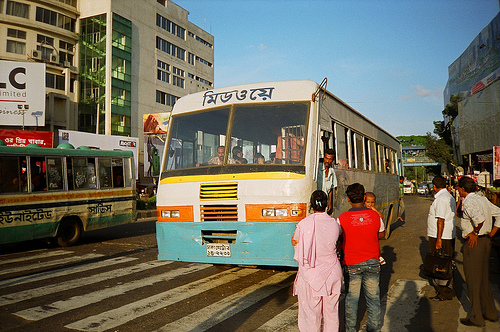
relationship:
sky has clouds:
[224, 17, 442, 110] [383, 76, 459, 108]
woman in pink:
[297, 187, 333, 330] [283, 200, 365, 323]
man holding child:
[336, 182, 389, 328] [365, 192, 376, 208]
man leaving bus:
[336, 182, 389, 328] [143, 71, 418, 243]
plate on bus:
[195, 240, 249, 269] [143, 71, 418, 243]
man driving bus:
[336, 182, 389, 328] [143, 71, 418, 243]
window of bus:
[232, 102, 314, 165] [143, 71, 418, 243]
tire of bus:
[52, 212, 85, 248] [3, 133, 142, 237]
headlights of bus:
[152, 206, 295, 221] [143, 71, 418, 243]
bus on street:
[143, 71, 418, 243] [133, 226, 179, 328]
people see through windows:
[285, 169, 493, 318] [161, 102, 317, 165]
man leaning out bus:
[311, 135, 342, 197] [300, 149, 323, 187]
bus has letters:
[143, 71, 418, 243] [191, 81, 291, 109]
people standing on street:
[285, 169, 493, 318] [133, 226, 179, 328]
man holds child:
[336, 182, 389, 328] [365, 192, 376, 208]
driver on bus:
[319, 149, 340, 193] [143, 71, 418, 243]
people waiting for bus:
[285, 169, 493, 318] [143, 71, 418, 243]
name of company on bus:
[191, 81, 291, 109] [161, 102, 317, 165]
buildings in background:
[78, 27, 231, 111] [12, 17, 236, 98]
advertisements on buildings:
[2, 65, 51, 133] [2, 12, 85, 153]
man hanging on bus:
[336, 182, 389, 328] [289, 142, 336, 210]